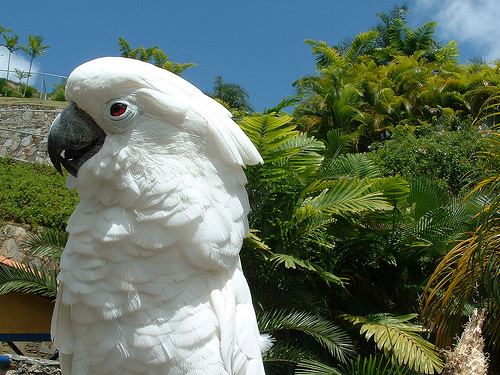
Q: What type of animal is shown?
A: Bird.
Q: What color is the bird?
A: White.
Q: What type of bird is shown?
A: Umbrella Cockatoo.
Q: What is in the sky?
A: Clouds.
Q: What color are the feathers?
A: White.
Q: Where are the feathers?
A: On bird.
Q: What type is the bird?
A: Umbrella cockatoo.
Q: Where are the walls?
A: Hillside.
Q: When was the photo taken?
A: Bright day.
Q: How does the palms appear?
A: Bushy.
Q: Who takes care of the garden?
A: Gardener.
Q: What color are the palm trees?
A: Green.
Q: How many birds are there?
A: 1.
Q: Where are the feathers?
A: On the bird.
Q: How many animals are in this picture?
A: One.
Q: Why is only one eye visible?
A: Bird is facing left.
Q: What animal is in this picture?
A: Bird.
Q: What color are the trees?
A: Green.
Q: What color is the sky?
A: Blue.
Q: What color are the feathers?
A: White.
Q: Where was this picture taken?
A: Zoo.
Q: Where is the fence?
A: Background.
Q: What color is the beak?
A: Black.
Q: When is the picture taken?
A: Daytime.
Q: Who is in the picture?
A: No one.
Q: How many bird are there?
A: 1.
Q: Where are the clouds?
A: In the sky.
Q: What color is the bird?
A: White.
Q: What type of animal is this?
A: A bird.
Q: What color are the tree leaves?
A: Green.